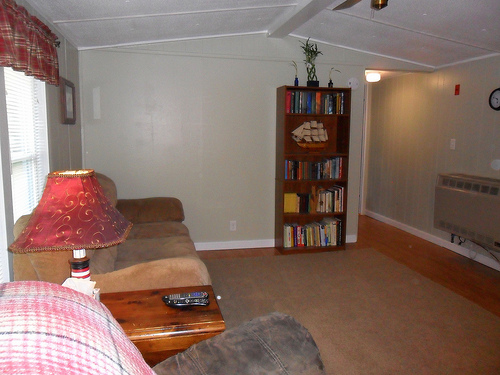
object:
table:
[95, 278, 224, 368]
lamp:
[7, 165, 133, 305]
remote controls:
[162, 288, 215, 305]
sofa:
[12, 167, 212, 300]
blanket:
[2, 278, 157, 374]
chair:
[0, 275, 331, 374]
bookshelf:
[271, 82, 352, 255]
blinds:
[5, 66, 54, 220]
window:
[1, 3, 69, 288]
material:
[2, 2, 62, 86]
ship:
[290, 116, 330, 146]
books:
[286, 86, 294, 113]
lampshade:
[8, 165, 136, 256]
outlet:
[227, 219, 240, 234]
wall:
[78, 34, 366, 251]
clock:
[488, 87, 499, 113]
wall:
[364, 55, 500, 319]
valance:
[1, 1, 62, 85]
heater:
[432, 167, 500, 254]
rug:
[197, 249, 500, 372]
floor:
[196, 213, 500, 374]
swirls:
[77, 205, 97, 225]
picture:
[60, 78, 80, 127]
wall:
[2, 1, 84, 289]